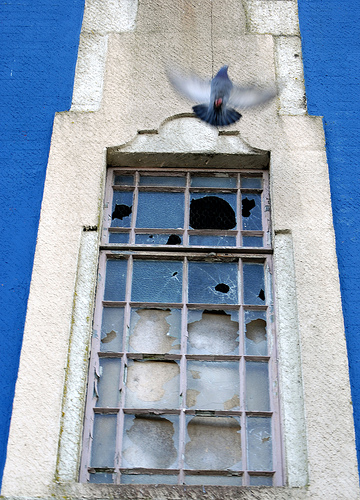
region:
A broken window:
[188, 177, 240, 254]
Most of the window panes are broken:
[89, 167, 290, 496]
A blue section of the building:
[8, 10, 67, 247]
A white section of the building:
[280, 194, 348, 444]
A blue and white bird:
[176, 69, 279, 137]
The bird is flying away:
[180, 44, 293, 141]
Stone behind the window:
[109, 319, 250, 457]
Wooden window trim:
[169, 251, 197, 478]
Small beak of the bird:
[224, 59, 231, 70]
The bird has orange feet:
[211, 90, 224, 110]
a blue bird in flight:
[149, 47, 290, 140]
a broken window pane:
[186, 188, 240, 233]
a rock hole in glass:
[209, 279, 235, 297]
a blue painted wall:
[0, 0, 86, 486]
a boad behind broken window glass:
[91, 305, 282, 479]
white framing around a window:
[64, 118, 305, 498]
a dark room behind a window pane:
[191, 198, 233, 231]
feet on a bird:
[213, 98, 222, 109]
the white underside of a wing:
[167, 68, 210, 104]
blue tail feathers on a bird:
[192, 103, 241, 128]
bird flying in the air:
[164, 47, 289, 137]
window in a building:
[94, 129, 293, 495]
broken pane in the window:
[122, 407, 184, 474]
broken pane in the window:
[183, 412, 243, 480]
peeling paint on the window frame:
[91, 357, 103, 408]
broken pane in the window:
[191, 265, 234, 310]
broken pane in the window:
[114, 189, 139, 241]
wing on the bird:
[238, 78, 284, 124]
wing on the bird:
[161, 56, 206, 107]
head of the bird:
[218, 59, 233, 77]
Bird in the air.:
[137, 43, 309, 161]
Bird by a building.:
[147, 46, 275, 153]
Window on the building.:
[84, 137, 354, 377]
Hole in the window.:
[147, 197, 342, 341]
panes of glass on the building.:
[99, 243, 318, 481]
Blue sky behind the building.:
[13, 14, 169, 152]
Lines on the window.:
[104, 279, 275, 431]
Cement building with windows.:
[270, 223, 359, 350]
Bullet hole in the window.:
[195, 275, 259, 302]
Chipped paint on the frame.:
[79, 358, 110, 392]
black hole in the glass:
[188, 190, 236, 235]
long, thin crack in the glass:
[191, 265, 219, 285]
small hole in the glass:
[167, 269, 180, 278]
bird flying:
[157, 57, 291, 130]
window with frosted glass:
[87, 138, 293, 491]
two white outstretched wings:
[159, 66, 291, 109]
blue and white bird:
[154, 49, 294, 129]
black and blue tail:
[193, 104, 244, 126]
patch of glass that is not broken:
[101, 255, 130, 302]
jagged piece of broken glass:
[161, 312, 175, 340]